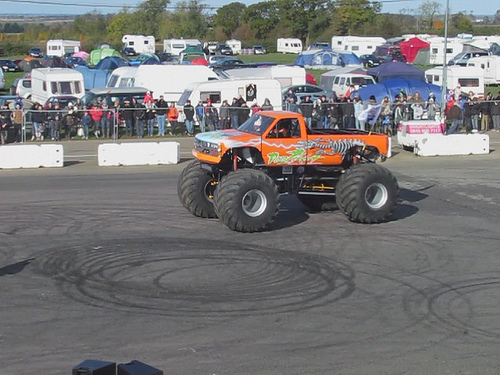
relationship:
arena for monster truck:
[6, 169, 497, 362] [179, 108, 405, 235]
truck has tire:
[179, 108, 405, 235] [216, 172, 275, 232]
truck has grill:
[179, 108, 405, 235] [190, 138, 222, 158]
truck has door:
[179, 108, 405, 235] [265, 138, 307, 166]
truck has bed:
[179, 108, 405, 235] [306, 131, 391, 169]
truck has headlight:
[179, 108, 405, 235] [210, 144, 224, 157]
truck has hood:
[179, 108, 405, 235] [197, 127, 254, 150]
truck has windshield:
[179, 108, 405, 235] [235, 116, 269, 135]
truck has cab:
[179, 108, 405, 235] [192, 113, 308, 171]